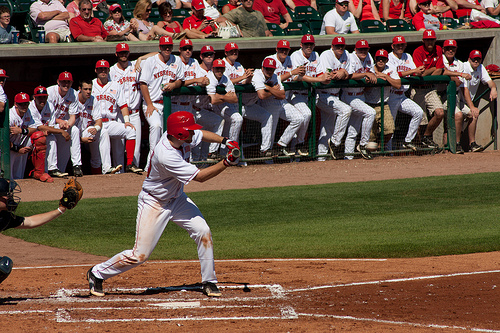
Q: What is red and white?
A: The uniform of the team up at bat.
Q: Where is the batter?
A: In the batting box.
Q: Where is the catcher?
A: Behind the batter.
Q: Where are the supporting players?
A: Leaning on the fence, beside the dugout.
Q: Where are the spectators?
A: In the stadium seats, above the dugout.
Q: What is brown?
A: The baseball diamond.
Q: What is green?
A: The grass surrounding the diamond.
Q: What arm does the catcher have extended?
A: The right arm.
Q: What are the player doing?
A: Playing baseball.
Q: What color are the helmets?
A: Red.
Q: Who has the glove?
A: The catcher.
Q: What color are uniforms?
A: White.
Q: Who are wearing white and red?
A: The baseball players.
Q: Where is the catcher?
A: Behind the batter.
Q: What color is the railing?
A: Green.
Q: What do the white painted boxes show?
A: The batter's boxes.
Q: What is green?
A: Grass.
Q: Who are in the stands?
A: Spectators.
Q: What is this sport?
A: Baseball.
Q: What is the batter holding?
A: Bat.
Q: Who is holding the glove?
A: Catcher.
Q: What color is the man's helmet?
A: Red.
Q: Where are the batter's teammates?
A: In the dugout.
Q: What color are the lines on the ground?
A: White.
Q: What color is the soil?
A: Brown.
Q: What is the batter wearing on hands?
A: Batting gloves.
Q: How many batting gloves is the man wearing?
A: Two.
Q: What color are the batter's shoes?
A: Black.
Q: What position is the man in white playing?
A: Batter.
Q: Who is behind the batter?
A: Catcher.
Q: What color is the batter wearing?
A: White.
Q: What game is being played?
A: Baseball.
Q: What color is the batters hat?
A: Red.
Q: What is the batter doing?
A: Swinging at a ball.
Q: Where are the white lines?
A: In the dirt.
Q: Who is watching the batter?
A: The teammates.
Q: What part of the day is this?
A: Daytime.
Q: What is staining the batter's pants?
A: Dirt.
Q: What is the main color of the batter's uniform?
A: White.